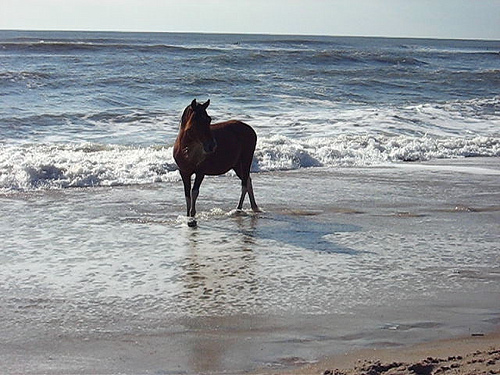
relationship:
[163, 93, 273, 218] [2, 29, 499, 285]
horse in ocean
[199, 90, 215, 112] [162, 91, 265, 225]
ear of horse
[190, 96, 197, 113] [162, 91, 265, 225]
ear of horse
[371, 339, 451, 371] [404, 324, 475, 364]
traces in sand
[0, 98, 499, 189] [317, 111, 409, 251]
waves in ocean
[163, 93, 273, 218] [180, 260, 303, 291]
horse at beach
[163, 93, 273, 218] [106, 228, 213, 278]
horse at water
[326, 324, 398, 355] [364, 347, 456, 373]
sand on beach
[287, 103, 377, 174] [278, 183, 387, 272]
waves coming into shore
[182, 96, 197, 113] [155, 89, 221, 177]
ear on head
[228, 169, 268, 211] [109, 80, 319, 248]
leg behind horse